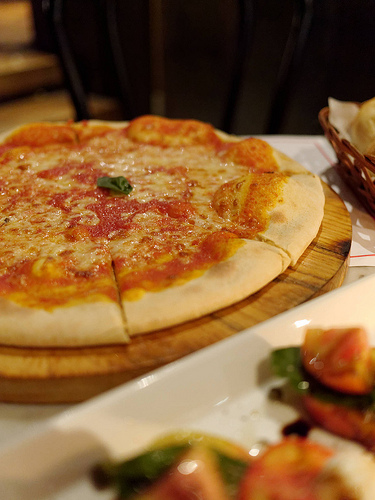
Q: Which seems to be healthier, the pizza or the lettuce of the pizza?
A: The lettuce is healthier than the pizza.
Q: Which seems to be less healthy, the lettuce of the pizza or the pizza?
A: The pizza is less healthy than the lettuce.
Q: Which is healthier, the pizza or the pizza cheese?
A: The cheese is healthier than the pizza.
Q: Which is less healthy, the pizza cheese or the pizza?
A: The pizza is less healthy than the cheese.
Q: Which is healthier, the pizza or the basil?
A: The basil is healthier than the pizza.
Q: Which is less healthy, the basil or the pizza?
A: The pizza is less healthy than the basil.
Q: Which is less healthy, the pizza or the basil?
A: The pizza is less healthy than the basil.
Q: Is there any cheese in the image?
A: Yes, there is cheese.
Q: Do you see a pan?
A: No, there are no pans.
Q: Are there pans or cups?
A: No, there are no pans or cups.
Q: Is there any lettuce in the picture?
A: Yes, there is lettuce.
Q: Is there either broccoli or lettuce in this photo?
A: Yes, there is lettuce.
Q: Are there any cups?
A: No, there are no cups.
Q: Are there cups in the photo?
A: No, there are no cups.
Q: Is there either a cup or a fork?
A: No, there are no cups or forks.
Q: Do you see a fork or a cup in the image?
A: No, there are no cups or forks.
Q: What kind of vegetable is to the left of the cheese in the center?
A: The vegetable is lettuce.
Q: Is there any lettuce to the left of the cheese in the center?
A: Yes, there is lettuce to the left of the cheese.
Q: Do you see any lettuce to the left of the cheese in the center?
A: Yes, there is lettuce to the left of the cheese.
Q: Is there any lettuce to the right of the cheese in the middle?
A: No, the lettuce is to the left of the cheese.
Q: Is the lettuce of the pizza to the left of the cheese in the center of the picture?
A: Yes, the lettuce is to the left of the cheese.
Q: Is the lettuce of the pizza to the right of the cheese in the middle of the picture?
A: No, the lettuce is to the left of the cheese.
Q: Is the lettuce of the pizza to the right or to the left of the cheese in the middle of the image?
A: The lettuce is to the left of the cheese.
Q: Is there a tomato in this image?
A: Yes, there is a tomato.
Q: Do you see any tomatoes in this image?
A: Yes, there is a tomato.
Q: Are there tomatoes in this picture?
A: Yes, there is a tomato.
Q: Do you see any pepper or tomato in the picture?
A: Yes, there is a tomato.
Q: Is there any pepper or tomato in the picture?
A: Yes, there is a tomato.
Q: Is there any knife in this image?
A: No, there are no knives.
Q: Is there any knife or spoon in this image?
A: No, there are no knives or spoons.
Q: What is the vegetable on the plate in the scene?
A: The vegetable is a tomato.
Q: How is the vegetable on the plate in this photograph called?
A: The vegetable is a tomato.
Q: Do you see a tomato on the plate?
A: Yes, there is a tomato on the plate.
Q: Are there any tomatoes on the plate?
A: Yes, there is a tomato on the plate.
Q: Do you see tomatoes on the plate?
A: Yes, there is a tomato on the plate.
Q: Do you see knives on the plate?
A: No, there is a tomato on the plate.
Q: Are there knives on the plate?
A: No, there is a tomato on the plate.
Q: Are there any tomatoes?
A: Yes, there is a tomato.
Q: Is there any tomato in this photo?
A: Yes, there is a tomato.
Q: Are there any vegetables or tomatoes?
A: Yes, there is a tomato.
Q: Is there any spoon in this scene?
A: No, there are no spoons.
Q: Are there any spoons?
A: No, there are no spoons.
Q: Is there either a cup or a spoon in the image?
A: No, there are no spoons or cups.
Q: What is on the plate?
A: The tomato is on the plate.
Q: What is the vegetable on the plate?
A: The vegetable is a tomato.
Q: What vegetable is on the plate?
A: The vegetable is a tomato.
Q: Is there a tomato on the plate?
A: Yes, there is a tomato on the plate.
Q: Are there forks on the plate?
A: No, there is a tomato on the plate.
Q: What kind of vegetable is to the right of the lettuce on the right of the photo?
A: The vegetable is a tomato.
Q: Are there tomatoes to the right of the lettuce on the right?
A: Yes, there is a tomato to the right of the lettuce.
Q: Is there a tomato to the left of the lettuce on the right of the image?
A: No, the tomato is to the right of the lettuce.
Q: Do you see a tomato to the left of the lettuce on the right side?
A: No, the tomato is to the right of the lettuce.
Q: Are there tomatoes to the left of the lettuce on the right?
A: No, the tomato is to the right of the lettuce.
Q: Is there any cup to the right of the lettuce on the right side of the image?
A: No, there is a tomato to the right of the lettuce.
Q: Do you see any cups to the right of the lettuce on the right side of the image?
A: No, there is a tomato to the right of the lettuce.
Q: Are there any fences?
A: No, there are no fences.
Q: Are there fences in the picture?
A: No, there are no fences.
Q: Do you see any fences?
A: No, there are no fences.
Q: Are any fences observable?
A: No, there are no fences.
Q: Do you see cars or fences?
A: No, there are no fences or cars.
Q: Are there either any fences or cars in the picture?
A: No, there are no fences or cars.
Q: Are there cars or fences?
A: No, there are no fences or cars.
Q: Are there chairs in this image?
A: Yes, there is a chair.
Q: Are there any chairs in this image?
A: Yes, there is a chair.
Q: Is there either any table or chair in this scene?
A: Yes, there is a chair.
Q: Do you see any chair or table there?
A: Yes, there is a chair.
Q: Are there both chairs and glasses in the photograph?
A: No, there is a chair but no glasses.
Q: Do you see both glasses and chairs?
A: No, there is a chair but no glasses.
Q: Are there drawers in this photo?
A: No, there are no drawers.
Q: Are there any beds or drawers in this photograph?
A: No, there are no drawers or beds.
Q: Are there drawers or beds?
A: No, there are no drawers or beds.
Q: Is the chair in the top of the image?
A: Yes, the chair is in the top of the image.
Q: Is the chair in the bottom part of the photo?
A: No, the chair is in the top of the image.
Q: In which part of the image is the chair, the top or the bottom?
A: The chair is in the top of the image.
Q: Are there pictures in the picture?
A: No, there are no pictures.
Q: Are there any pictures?
A: No, there are no pictures.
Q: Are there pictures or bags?
A: No, there are no pictures or bags.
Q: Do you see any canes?
A: No, there are no canes.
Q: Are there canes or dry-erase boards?
A: No, there are no canes or dry-erase boards.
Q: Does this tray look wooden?
A: Yes, the tray is wooden.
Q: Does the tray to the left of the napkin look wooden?
A: Yes, the tray is wooden.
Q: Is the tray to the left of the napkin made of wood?
A: Yes, the tray is made of wood.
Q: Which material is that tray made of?
A: The tray is made of wood.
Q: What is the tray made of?
A: The tray is made of wood.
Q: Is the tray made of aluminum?
A: No, the tray is made of wood.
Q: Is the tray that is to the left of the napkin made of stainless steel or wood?
A: The tray is made of wood.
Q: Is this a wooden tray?
A: Yes, this is a wooden tray.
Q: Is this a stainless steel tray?
A: No, this is a wooden tray.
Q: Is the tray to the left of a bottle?
A: No, the tray is to the left of the napkin.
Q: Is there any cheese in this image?
A: Yes, there is cheese.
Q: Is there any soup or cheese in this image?
A: Yes, there is cheese.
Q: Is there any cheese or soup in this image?
A: Yes, there is cheese.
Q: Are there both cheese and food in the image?
A: Yes, there are both cheese and food.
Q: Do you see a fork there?
A: No, there are no forks.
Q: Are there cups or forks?
A: No, there are no forks or cups.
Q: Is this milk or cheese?
A: This is cheese.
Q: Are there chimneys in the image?
A: No, there are no chimneys.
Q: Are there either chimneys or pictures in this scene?
A: No, there are no chimneys or pictures.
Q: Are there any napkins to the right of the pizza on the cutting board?
A: Yes, there is a napkin to the right of the pizza.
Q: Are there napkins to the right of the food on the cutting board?
A: Yes, there is a napkin to the right of the pizza.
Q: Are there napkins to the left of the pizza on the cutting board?
A: No, the napkin is to the right of the pizza.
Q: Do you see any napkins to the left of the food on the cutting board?
A: No, the napkin is to the right of the pizza.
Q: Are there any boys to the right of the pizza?
A: No, there is a napkin to the right of the pizza.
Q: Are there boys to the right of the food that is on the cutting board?
A: No, there is a napkin to the right of the pizza.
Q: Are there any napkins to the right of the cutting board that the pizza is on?
A: Yes, there is a napkin to the right of the cutting board.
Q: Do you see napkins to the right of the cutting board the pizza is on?
A: Yes, there is a napkin to the right of the cutting board.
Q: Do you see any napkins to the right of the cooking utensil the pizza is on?
A: Yes, there is a napkin to the right of the cutting board.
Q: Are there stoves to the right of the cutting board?
A: No, there is a napkin to the right of the cutting board.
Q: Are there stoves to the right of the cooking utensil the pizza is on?
A: No, there is a napkin to the right of the cutting board.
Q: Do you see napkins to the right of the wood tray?
A: Yes, there is a napkin to the right of the tray.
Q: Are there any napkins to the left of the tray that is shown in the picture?
A: No, the napkin is to the right of the tray.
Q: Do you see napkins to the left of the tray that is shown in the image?
A: No, the napkin is to the right of the tray.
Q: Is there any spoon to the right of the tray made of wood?
A: No, there is a napkin to the right of the tray.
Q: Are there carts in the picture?
A: No, there are no carts.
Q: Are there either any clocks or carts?
A: No, there are no carts or clocks.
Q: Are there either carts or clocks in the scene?
A: No, there are no carts or clocks.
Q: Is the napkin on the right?
A: Yes, the napkin is on the right of the image.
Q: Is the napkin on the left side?
A: No, the napkin is on the right of the image.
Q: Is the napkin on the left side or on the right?
A: The napkin is on the right of the image.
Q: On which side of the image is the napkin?
A: The napkin is on the right of the image.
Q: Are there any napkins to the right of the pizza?
A: Yes, there is a napkin to the right of the pizza.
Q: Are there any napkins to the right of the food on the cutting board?
A: Yes, there is a napkin to the right of the pizza.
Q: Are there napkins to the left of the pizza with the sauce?
A: No, the napkin is to the right of the pizza.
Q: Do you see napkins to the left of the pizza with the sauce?
A: No, the napkin is to the right of the pizza.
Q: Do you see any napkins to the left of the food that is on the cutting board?
A: No, the napkin is to the right of the pizza.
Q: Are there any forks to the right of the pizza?
A: No, there is a napkin to the right of the pizza.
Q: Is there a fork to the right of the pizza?
A: No, there is a napkin to the right of the pizza.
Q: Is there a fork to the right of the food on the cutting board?
A: No, there is a napkin to the right of the pizza.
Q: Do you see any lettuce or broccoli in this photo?
A: Yes, there is lettuce.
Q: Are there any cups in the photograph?
A: No, there are no cups.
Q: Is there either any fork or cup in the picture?
A: No, there are no cups or forks.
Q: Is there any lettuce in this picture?
A: Yes, there is lettuce.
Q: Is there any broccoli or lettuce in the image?
A: Yes, there is lettuce.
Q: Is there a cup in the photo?
A: No, there are no cups.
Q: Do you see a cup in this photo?
A: No, there are no cups.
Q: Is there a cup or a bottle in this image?
A: No, there are no cups or bottles.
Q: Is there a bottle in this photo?
A: No, there are no bottles.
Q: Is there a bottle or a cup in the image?
A: No, there are no bottles or cups.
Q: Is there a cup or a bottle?
A: No, there are no bottles or cups.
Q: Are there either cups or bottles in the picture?
A: No, there are no bottles or cups.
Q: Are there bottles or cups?
A: No, there are no bottles or cups.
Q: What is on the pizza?
A: The sauce is on the pizza.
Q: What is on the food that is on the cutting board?
A: The sauce is on the pizza.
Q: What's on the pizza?
A: The sauce is on the pizza.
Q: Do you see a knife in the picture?
A: No, there are no knives.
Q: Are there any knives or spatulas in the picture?
A: No, there are no knives or spatulas.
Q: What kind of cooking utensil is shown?
A: The cooking utensil is a cutting board.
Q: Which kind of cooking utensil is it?
A: The cooking utensil is a cutting board.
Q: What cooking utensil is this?
A: That is a cutting board.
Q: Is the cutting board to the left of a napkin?
A: Yes, the cutting board is to the left of a napkin.